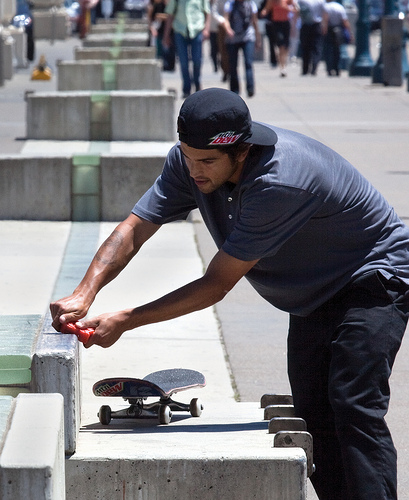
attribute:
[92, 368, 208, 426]
skate board — black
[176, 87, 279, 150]
hat — backwards, black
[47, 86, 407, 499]
man — bending over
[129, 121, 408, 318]
shirt — blue, gray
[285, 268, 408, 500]
pants — dark blue, black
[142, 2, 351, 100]
people — walking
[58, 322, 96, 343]
object — orange, red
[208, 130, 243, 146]
letters — green, red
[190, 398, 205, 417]
wheel — plastic, white, black, silver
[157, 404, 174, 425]
wheel — black, silver, plastic, white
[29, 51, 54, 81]
object — yellow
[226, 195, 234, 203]
button — silver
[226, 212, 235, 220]
button — silver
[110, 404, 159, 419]
axel — silver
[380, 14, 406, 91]
pole — here